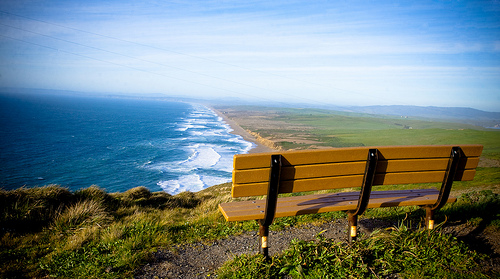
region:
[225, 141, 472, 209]
brown wooden bench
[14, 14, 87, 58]
white clouds in blue sky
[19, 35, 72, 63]
white clouds in blue sky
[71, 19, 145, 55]
white clouds in blue sky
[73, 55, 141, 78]
white clouds in blue sky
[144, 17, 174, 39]
white clouds in blue sky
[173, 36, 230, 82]
white clouds in blue sky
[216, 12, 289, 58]
white clouds in blue sky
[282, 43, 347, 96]
white clouds in blue sky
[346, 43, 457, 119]
white clouds in blue sky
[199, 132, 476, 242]
a bench facing the sea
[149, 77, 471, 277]
a bench facing the sea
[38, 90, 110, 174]
the sea is blue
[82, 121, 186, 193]
the sea is blue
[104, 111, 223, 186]
the sea is blue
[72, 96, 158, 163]
the sea is blue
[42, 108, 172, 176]
the sea is blue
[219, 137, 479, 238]
brown wooden bench on bluff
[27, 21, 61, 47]
white clouds in blue sky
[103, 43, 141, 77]
white clouds in blue sky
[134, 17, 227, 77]
white clouds in blue sky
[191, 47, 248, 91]
v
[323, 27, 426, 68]
white clouds in blue sky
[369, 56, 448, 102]
white clouds in blue sky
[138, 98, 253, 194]
Waves in the ocean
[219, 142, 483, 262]
A brown wooden bench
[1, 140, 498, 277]
Bench on a cliffside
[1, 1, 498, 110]
White clouds in the sky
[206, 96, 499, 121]
Mountains in the far distance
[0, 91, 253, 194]
A bright blue ocean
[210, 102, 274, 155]
Sand on the beach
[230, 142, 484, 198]
Wooden beams on the bench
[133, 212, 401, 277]
Gravel on the ground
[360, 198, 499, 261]
Shadows on the ground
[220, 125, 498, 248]
a bench with a veiw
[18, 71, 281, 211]
a beautiful view of the ocean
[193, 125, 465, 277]
a brown bench with black supports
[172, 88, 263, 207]
foamy white water coming to shore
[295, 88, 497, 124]
a mountain in the distance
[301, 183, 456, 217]
shadow of top half of bench on lower half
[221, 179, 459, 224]
a seat to a bench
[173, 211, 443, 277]
a worn dirt patch in front of bench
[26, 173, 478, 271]
grass around the bench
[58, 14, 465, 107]
white clouds in the sky